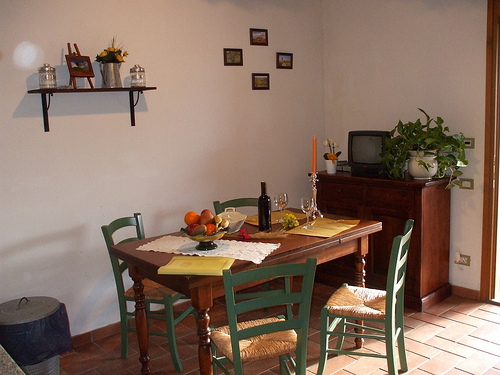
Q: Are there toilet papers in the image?
A: No, there are no toilet papers.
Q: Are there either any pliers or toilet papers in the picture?
A: No, there are no toilet papers or pliers.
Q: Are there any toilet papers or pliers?
A: No, there are no toilet papers or pliers.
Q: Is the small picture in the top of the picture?
A: Yes, the picture is in the top of the image.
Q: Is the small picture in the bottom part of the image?
A: No, the picture is in the top of the image.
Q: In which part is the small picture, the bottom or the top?
A: The picture is in the top of the image.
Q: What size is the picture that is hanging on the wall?
A: The picture is small.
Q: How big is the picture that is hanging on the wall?
A: The picture is small.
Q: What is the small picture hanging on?
A: The picture is hanging on the wall.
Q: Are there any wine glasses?
A: Yes, there is a wine glass.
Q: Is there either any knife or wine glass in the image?
A: Yes, there is a wine glass.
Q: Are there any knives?
A: No, there are no knives.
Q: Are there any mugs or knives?
A: No, there are no knives or mugs.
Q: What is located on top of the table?
A: The wine glass is on top of the table.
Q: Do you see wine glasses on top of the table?
A: Yes, there is a wine glass on top of the table.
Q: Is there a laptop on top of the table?
A: No, there is a wine glass on top of the table.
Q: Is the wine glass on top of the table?
A: Yes, the wine glass is on top of the table.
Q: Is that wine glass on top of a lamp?
A: No, the wine glass is on top of the table.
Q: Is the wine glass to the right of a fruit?
A: Yes, the wine glass is to the right of a fruit.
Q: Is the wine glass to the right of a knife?
A: No, the wine glass is to the right of a fruit.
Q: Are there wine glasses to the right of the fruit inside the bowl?
A: Yes, there is a wine glass to the right of the fruit.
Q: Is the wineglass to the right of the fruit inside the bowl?
A: Yes, the wineglass is to the right of the fruit.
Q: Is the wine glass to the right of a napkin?
A: No, the wine glass is to the right of the fruit.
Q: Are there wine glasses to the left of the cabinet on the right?
A: Yes, there is a wine glass to the left of the cabinet.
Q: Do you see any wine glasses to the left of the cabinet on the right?
A: Yes, there is a wine glass to the left of the cabinet.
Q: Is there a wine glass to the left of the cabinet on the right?
A: Yes, there is a wine glass to the left of the cabinet.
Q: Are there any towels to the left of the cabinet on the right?
A: No, there is a wine glass to the left of the cabinet.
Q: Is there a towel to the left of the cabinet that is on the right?
A: No, there is a wine glass to the left of the cabinet.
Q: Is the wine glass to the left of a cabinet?
A: Yes, the wine glass is to the left of a cabinet.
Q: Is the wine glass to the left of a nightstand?
A: No, the wine glass is to the left of a cabinet.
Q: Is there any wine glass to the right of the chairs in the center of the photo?
A: Yes, there is a wine glass to the right of the chairs.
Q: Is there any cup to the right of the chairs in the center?
A: No, there is a wine glass to the right of the chairs.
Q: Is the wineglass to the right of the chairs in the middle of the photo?
A: Yes, the wineglass is to the right of the chairs.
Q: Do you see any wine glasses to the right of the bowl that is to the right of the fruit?
A: Yes, there is a wine glass to the right of the bowl.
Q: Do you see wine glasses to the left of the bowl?
A: No, the wine glass is to the right of the bowl.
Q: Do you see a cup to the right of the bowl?
A: No, there is a wine glass to the right of the bowl.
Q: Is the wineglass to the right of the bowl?
A: Yes, the wineglass is to the right of the bowl.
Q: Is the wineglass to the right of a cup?
A: No, the wineglass is to the right of the bowl.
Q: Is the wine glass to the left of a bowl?
A: No, the wine glass is to the right of a bowl.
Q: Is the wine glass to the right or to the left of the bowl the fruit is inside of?
A: The wine glass is to the right of the bowl.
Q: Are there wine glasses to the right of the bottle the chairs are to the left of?
A: Yes, there is a wine glass to the right of the bottle.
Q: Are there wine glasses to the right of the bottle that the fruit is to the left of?
A: Yes, there is a wine glass to the right of the bottle.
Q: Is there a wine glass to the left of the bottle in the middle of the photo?
A: No, the wine glass is to the right of the bottle.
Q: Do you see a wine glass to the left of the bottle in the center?
A: No, the wine glass is to the right of the bottle.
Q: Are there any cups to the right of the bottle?
A: No, there is a wine glass to the right of the bottle.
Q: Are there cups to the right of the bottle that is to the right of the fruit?
A: No, there is a wine glass to the right of the bottle.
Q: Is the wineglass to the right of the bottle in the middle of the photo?
A: Yes, the wineglass is to the right of the bottle.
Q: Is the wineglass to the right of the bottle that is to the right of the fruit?
A: Yes, the wineglass is to the right of the bottle.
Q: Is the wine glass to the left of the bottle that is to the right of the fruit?
A: No, the wine glass is to the right of the bottle.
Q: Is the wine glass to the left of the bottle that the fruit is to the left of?
A: No, the wine glass is to the right of the bottle.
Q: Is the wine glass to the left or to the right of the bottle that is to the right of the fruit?
A: The wine glass is to the right of the bottle.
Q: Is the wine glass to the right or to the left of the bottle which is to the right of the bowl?
A: The wine glass is to the right of the bottle.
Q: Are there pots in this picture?
A: Yes, there is a pot.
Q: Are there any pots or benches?
A: Yes, there is a pot.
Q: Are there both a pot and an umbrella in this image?
A: No, there is a pot but no umbrellas.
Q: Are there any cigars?
A: No, there are no cigars.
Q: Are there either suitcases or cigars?
A: No, there are no cigars or suitcases.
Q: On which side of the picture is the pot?
A: The pot is on the right of the image.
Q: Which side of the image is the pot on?
A: The pot is on the right of the image.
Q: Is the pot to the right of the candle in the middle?
A: Yes, the pot is to the right of the candle.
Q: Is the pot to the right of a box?
A: No, the pot is to the right of the candle.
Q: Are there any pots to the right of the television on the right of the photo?
A: Yes, there is a pot to the right of the TV.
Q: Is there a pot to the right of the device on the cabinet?
A: Yes, there is a pot to the right of the TV.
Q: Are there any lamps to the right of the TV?
A: No, there is a pot to the right of the TV.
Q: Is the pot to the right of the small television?
A: Yes, the pot is to the right of the TV.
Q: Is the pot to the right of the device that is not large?
A: Yes, the pot is to the right of the TV.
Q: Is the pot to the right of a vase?
A: No, the pot is to the right of the TV.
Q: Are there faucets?
A: No, there are no faucets.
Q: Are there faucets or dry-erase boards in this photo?
A: No, there are no faucets or dry-erase boards.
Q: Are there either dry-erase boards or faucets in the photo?
A: No, there are no faucets or dry-erase boards.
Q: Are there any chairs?
A: Yes, there is a chair.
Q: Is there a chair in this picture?
A: Yes, there is a chair.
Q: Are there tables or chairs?
A: Yes, there is a chair.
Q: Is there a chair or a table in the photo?
A: Yes, there is a chair.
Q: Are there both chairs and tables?
A: Yes, there are both a chair and a table.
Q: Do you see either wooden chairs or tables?
A: Yes, there is a wood chair.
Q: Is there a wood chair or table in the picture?
A: Yes, there is a wood chair.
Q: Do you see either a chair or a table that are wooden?
A: Yes, the chair is wooden.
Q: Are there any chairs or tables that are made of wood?
A: Yes, the chair is made of wood.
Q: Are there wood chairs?
A: Yes, there is a chair that is made of wood.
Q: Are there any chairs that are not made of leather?
A: Yes, there is a chair that is made of wood.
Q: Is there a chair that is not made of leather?
A: Yes, there is a chair that is made of wood.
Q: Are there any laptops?
A: No, there are no laptops.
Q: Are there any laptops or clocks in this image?
A: No, there are no laptops or clocks.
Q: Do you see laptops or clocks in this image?
A: No, there are no laptops or clocks.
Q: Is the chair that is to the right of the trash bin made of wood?
A: Yes, the chair is made of wood.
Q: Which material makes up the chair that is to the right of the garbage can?
A: The chair is made of wood.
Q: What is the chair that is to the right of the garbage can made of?
A: The chair is made of wood.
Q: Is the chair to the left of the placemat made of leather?
A: No, the chair is made of wood.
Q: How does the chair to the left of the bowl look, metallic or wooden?
A: The chair is wooden.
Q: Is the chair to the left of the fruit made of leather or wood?
A: The chair is made of wood.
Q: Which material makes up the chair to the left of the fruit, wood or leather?
A: The chair is made of wood.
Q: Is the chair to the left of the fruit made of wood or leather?
A: The chair is made of wood.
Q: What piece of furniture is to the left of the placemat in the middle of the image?
A: The piece of furniture is a chair.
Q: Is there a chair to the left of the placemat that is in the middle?
A: Yes, there is a chair to the left of the placemat.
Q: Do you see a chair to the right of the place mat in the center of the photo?
A: No, the chair is to the left of the placemat.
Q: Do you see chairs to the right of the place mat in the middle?
A: No, the chair is to the left of the placemat.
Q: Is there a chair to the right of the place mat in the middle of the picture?
A: No, the chair is to the left of the placemat.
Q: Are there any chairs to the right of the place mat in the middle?
A: No, the chair is to the left of the placemat.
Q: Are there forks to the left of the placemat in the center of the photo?
A: No, there is a chair to the left of the placemat.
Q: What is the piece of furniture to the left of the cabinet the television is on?
A: The piece of furniture is a chair.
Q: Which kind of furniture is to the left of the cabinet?
A: The piece of furniture is a chair.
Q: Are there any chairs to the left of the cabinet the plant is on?
A: Yes, there is a chair to the left of the cabinet.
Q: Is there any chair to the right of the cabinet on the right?
A: No, the chair is to the left of the cabinet.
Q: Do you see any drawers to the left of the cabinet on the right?
A: No, there is a chair to the left of the cabinet.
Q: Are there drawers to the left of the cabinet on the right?
A: No, there is a chair to the left of the cabinet.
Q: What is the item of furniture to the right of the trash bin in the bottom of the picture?
A: The piece of furniture is a chair.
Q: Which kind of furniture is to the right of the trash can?
A: The piece of furniture is a chair.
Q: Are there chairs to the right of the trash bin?
A: Yes, there is a chair to the right of the trash bin.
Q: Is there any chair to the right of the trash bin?
A: Yes, there is a chair to the right of the trash bin.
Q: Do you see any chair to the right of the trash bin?
A: Yes, there is a chair to the right of the trash bin.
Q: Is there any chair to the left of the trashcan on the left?
A: No, the chair is to the right of the garbage bin.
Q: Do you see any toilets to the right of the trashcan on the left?
A: No, there is a chair to the right of the trashcan.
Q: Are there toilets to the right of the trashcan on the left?
A: No, there is a chair to the right of the trashcan.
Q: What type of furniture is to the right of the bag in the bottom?
A: The piece of furniture is a chair.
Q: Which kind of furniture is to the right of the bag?
A: The piece of furniture is a chair.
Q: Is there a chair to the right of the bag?
A: Yes, there is a chair to the right of the bag.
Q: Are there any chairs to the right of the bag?
A: Yes, there is a chair to the right of the bag.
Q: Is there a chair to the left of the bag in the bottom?
A: No, the chair is to the right of the bag.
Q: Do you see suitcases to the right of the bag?
A: No, there is a chair to the right of the bag.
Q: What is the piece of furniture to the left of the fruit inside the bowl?
A: The piece of furniture is a chair.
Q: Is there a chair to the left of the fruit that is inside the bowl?
A: Yes, there is a chair to the left of the fruit.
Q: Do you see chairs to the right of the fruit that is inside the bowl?
A: No, the chair is to the left of the fruit.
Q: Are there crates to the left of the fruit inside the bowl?
A: No, there is a chair to the left of the fruit.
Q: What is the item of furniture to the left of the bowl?
A: The piece of furniture is a chair.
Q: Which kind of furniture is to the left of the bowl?
A: The piece of furniture is a chair.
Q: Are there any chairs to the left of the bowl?
A: Yes, there is a chair to the left of the bowl.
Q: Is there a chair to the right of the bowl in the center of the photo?
A: No, the chair is to the left of the bowl.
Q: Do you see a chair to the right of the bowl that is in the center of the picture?
A: No, the chair is to the left of the bowl.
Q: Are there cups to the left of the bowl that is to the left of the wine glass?
A: No, there is a chair to the left of the bowl.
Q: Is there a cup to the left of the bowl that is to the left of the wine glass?
A: No, there is a chair to the left of the bowl.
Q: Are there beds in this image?
A: No, there are no beds.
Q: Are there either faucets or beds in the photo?
A: No, there are no beds or faucets.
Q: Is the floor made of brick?
A: Yes, the floor is made of brick.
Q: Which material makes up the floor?
A: The floor is made of brick.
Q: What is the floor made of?
A: The floor is made of brick.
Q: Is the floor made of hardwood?
A: No, the floor is made of brick.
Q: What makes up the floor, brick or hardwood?
A: The floor is made of brick.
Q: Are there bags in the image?
A: Yes, there is a bag.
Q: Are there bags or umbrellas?
A: Yes, there is a bag.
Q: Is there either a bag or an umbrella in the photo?
A: Yes, there is a bag.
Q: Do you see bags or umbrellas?
A: Yes, there is a bag.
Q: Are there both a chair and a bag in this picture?
A: Yes, there are both a bag and a chair.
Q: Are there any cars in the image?
A: No, there are no cars.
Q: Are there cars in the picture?
A: No, there are no cars.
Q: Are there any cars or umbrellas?
A: No, there are no cars or umbrellas.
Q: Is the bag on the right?
A: No, the bag is on the left of the image.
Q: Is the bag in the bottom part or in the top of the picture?
A: The bag is in the bottom of the image.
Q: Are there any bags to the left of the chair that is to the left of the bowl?
A: Yes, there is a bag to the left of the chair.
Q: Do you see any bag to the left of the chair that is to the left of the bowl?
A: Yes, there is a bag to the left of the chair.